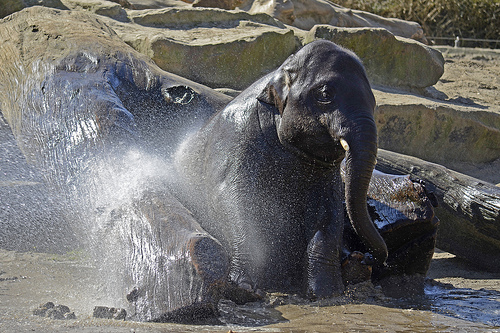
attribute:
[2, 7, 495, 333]
tree trunk — cut, black, wet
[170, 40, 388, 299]
elephant — gray, sitting, wet, young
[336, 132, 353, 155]
tusk — white, small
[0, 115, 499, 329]
water — misty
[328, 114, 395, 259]
trunk — long, thick, gray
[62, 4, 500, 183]
rocks — gray, tan, large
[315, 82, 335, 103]
eye — black, round, small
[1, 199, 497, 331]
ground — wet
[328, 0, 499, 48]
bushes — green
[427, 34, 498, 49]
guard wire — white